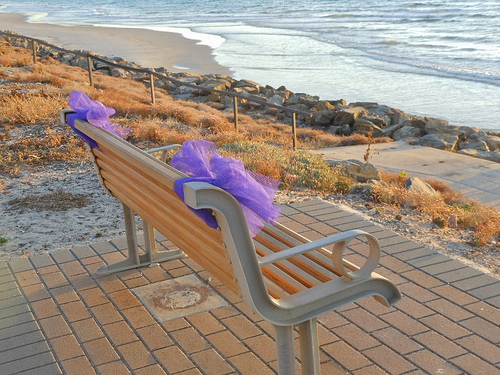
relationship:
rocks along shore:
[45, 31, 497, 177] [5, 11, 497, 224]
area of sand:
[0, 154, 123, 261] [20, 198, 89, 239]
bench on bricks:
[65, 93, 415, 365] [12, 212, 497, 372]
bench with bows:
[65, 93, 415, 365] [57, 85, 279, 224]